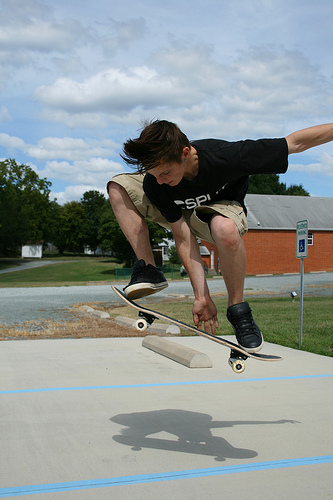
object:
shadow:
[102, 408, 301, 463]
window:
[306, 234, 313, 243]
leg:
[102, 169, 154, 266]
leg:
[209, 200, 247, 309]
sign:
[295, 220, 308, 257]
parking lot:
[0, 332, 332, 497]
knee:
[106, 177, 136, 212]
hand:
[191, 296, 219, 333]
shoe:
[123, 261, 170, 299]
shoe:
[223, 299, 267, 351]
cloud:
[0, 1, 146, 93]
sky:
[0, 0, 332, 205]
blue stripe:
[0, 371, 332, 395]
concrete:
[0, 335, 332, 499]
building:
[193, 191, 331, 276]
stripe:
[1, 455, 332, 496]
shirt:
[141, 138, 290, 225]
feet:
[224, 300, 263, 354]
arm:
[145, 188, 211, 300]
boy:
[106, 117, 332, 356]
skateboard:
[110, 286, 283, 374]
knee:
[213, 215, 240, 244]